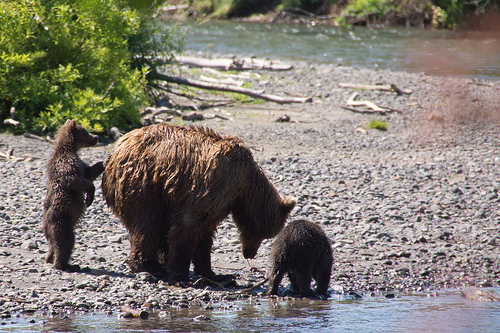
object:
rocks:
[383, 292, 395, 301]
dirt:
[404, 70, 499, 142]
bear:
[100, 122, 299, 289]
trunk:
[150, 71, 314, 105]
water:
[0, 287, 499, 332]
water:
[148, 12, 499, 86]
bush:
[2, 1, 190, 147]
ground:
[0, 47, 499, 316]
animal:
[268, 217, 334, 300]